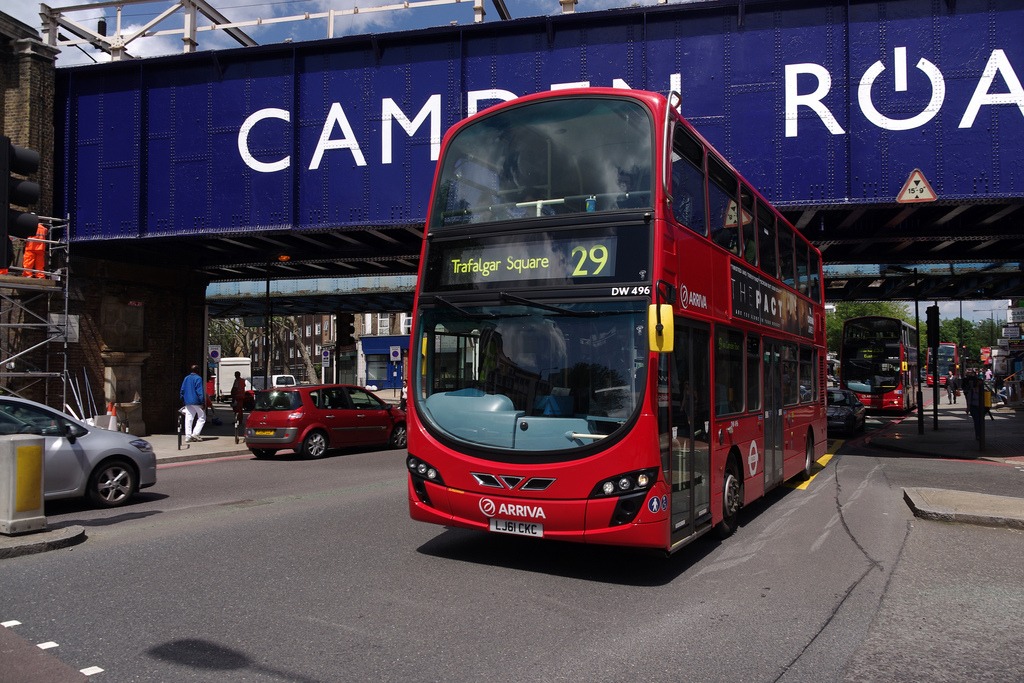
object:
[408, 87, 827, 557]
doubledecker bus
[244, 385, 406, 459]
car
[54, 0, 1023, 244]
overpass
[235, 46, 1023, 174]
letters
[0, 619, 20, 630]
square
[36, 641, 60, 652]
square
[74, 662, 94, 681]
square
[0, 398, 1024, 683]
road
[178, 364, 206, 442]
man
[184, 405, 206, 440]
pants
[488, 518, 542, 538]
license plate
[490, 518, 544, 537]
letters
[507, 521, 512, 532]
numbers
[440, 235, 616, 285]
sign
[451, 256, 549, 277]
letters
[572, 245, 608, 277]
numbers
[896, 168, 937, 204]
sign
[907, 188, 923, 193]
letters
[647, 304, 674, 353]
side mirror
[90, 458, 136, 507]
tire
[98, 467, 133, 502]
rim